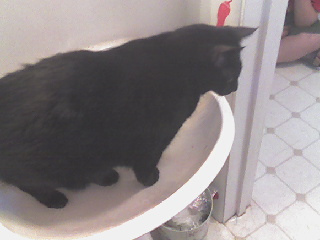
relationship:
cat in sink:
[0, 25, 261, 211] [1, 38, 237, 240]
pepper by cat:
[216, 0, 233, 27] [0, 25, 261, 211]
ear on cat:
[232, 25, 259, 40] [0, 25, 261, 211]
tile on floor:
[250, 171, 300, 219] [203, 63, 319, 239]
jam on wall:
[212, 0, 289, 223] [0, 0, 201, 75]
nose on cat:
[232, 84, 238, 95] [0, 25, 261, 211]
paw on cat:
[139, 167, 160, 187] [0, 25, 261, 211]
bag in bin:
[161, 185, 218, 233] [156, 186, 214, 240]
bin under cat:
[156, 186, 214, 240] [0, 25, 261, 211]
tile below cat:
[250, 171, 300, 219] [0, 25, 261, 211]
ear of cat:
[232, 25, 259, 40] [0, 25, 261, 211]